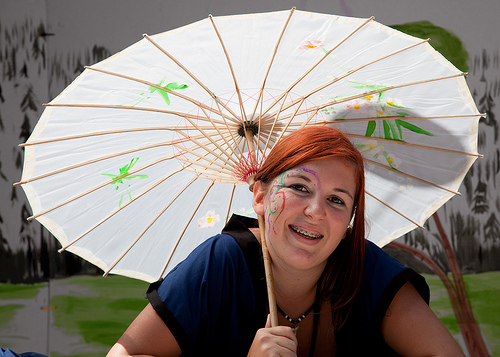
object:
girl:
[103, 127, 468, 357]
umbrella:
[12, 7, 487, 328]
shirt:
[144, 214, 431, 356]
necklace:
[276, 296, 323, 335]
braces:
[291, 225, 322, 241]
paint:
[266, 165, 321, 236]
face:
[254, 153, 359, 271]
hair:
[255, 124, 365, 333]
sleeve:
[146, 232, 236, 356]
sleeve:
[354, 237, 430, 356]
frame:
[13, 6, 488, 285]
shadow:
[328, 100, 468, 190]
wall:
[0, 0, 499, 356]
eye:
[287, 183, 309, 192]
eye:
[327, 195, 346, 206]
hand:
[248, 312, 296, 356]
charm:
[293, 326, 299, 335]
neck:
[266, 244, 330, 310]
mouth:
[288, 222, 325, 245]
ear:
[253, 179, 265, 215]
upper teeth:
[290, 224, 323, 238]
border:
[147, 279, 190, 356]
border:
[223, 212, 271, 326]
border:
[372, 267, 430, 353]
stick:
[246, 130, 279, 327]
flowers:
[341, 80, 437, 142]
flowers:
[298, 37, 330, 57]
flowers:
[128, 78, 188, 110]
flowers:
[101, 157, 148, 207]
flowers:
[197, 209, 220, 229]